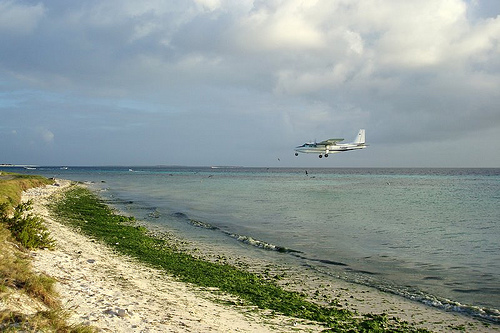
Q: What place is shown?
A: It is a sea.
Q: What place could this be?
A: It is a sea.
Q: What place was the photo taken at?
A: It was taken at the sea.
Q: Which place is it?
A: It is a sea.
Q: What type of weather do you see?
A: It is cloudy.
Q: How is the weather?
A: It is cloudy.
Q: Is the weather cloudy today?
A: Yes, it is cloudy.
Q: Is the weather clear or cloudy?
A: It is cloudy.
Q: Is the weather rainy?
A: No, it is cloudy.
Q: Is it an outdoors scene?
A: Yes, it is outdoors.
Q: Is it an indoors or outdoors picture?
A: It is outdoors.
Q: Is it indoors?
A: No, it is outdoors.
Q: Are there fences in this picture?
A: No, there are no fences.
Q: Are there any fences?
A: No, there are no fences.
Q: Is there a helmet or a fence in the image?
A: No, there are no fences or helmets.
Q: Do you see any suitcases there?
A: No, there are no suitcases.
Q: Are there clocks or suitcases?
A: No, there are no suitcases or clocks.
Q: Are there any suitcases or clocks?
A: No, there are no suitcases or clocks.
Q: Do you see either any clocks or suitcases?
A: No, there are no suitcases or clocks.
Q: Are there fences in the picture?
A: No, there are no fences.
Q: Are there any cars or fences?
A: No, there are no fences or cars.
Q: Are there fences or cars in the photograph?
A: No, there are no fences or cars.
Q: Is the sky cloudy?
A: Yes, the sky is cloudy.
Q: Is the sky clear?
A: No, the sky is cloudy.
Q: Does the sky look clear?
A: No, the sky is cloudy.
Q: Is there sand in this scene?
A: Yes, there is sand.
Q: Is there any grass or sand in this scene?
A: Yes, there is sand.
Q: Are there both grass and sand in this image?
A: Yes, there are both sand and grass.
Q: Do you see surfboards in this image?
A: No, there are no surfboards.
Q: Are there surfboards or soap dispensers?
A: No, there are no surfboards or soap dispensers.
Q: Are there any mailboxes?
A: No, there are no mailboxes.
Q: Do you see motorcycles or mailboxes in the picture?
A: No, there are no mailboxes or motorcycles.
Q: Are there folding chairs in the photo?
A: No, there are no folding chairs.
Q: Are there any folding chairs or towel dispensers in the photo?
A: No, there are no folding chairs or towel dispensers.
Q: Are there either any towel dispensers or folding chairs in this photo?
A: No, there are no folding chairs or towel dispensers.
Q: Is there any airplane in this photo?
A: Yes, there is an airplane.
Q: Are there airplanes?
A: Yes, there is an airplane.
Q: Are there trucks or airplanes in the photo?
A: Yes, there is an airplane.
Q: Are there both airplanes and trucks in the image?
A: No, there is an airplane but no trucks.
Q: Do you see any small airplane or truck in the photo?
A: Yes, there is a small airplane.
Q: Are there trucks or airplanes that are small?
A: Yes, the airplane is small.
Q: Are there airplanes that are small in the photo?
A: Yes, there is a small airplane.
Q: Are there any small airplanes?
A: Yes, there is a small airplane.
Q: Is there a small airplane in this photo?
A: Yes, there is a small airplane.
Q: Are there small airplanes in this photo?
A: Yes, there is a small airplane.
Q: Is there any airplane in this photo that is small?
A: Yes, there is an airplane that is small.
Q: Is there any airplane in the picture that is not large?
A: Yes, there is a small airplane.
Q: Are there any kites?
A: No, there are no kites.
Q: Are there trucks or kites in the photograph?
A: No, there are no kites or trucks.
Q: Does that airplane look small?
A: Yes, the airplane is small.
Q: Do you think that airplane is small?
A: Yes, the airplane is small.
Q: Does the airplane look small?
A: Yes, the airplane is small.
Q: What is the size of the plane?
A: The plane is small.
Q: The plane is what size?
A: The plane is small.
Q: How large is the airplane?
A: The airplane is small.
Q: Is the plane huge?
A: No, the plane is small.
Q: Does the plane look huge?
A: No, the plane is small.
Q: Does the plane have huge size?
A: No, the plane is small.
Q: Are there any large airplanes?
A: No, there is an airplane but it is small.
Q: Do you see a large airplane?
A: No, there is an airplane but it is small.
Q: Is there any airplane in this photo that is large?
A: No, there is an airplane but it is small.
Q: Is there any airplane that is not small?
A: No, there is an airplane but it is small.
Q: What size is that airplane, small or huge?
A: The airplane is small.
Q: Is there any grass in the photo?
A: Yes, there is grass.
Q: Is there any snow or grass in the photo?
A: Yes, there is grass.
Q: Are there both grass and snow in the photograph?
A: No, there is grass but no snow.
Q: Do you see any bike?
A: No, there are no bikes.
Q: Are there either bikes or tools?
A: No, there are no bikes or tools.